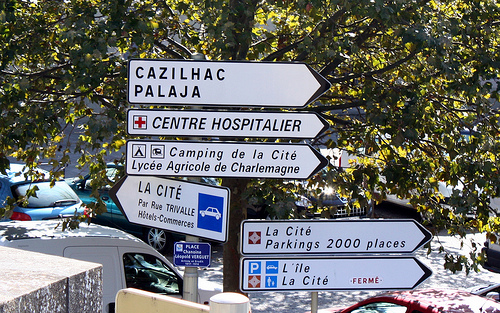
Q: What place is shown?
A: It is a parking lot.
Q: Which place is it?
A: It is a parking lot.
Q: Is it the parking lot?
A: Yes, it is the parking lot.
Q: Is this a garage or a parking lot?
A: It is a parking lot.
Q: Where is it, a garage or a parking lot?
A: It is a parking lot.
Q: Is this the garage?
A: No, it is the parking lot.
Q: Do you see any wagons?
A: No, there are no wagons.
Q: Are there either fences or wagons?
A: No, there are no wagons or fences.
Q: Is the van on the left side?
A: Yes, the van is on the left of the image.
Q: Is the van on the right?
A: No, the van is on the left of the image.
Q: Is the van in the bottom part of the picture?
A: Yes, the van is in the bottom of the image.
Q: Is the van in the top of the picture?
A: No, the van is in the bottom of the image.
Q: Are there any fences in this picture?
A: No, there are no fences.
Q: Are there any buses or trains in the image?
A: No, there are no buses or trains.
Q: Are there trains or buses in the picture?
A: No, there are no buses or trains.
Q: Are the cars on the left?
A: Yes, the cars are on the left of the image.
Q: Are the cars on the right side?
A: No, the cars are on the left of the image.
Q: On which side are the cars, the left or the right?
A: The cars are on the left of the image.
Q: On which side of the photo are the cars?
A: The cars are on the left of the image.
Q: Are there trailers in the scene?
A: No, there are no trailers.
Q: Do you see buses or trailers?
A: No, there are no trailers or buses.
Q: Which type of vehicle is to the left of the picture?
A: The vehicle is a car.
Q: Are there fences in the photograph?
A: No, there are no fences.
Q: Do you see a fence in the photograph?
A: No, there are no fences.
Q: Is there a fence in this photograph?
A: No, there are no fences.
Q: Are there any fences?
A: No, there are no fences.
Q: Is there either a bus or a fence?
A: No, there are no fences or buses.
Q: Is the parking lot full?
A: Yes, the parking lot is full.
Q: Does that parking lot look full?
A: Yes, the parking lot is full.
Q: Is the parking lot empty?
A: No, the parking lot is full.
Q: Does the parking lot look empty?
A: No, the parking lot is full.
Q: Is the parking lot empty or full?
A: The parking lot is full.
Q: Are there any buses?
A: No, there are no buses.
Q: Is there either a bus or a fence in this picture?
A: No, there are no buses or fences.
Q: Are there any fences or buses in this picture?
A: No, there are no buses or fences.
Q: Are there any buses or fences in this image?
A: No, there are no buses or fences.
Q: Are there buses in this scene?
A: No, there are no buses.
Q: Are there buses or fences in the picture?
A: No, there are no buses or fences.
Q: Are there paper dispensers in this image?
A: No, there are no paper dispensers.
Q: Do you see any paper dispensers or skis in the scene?
A: No, there are no paper dispensers or skis.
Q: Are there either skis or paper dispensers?
A: No, there are no paper dispensers or skis.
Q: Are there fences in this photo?
A: No, there are no fences.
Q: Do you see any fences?
A: No, there are no fences.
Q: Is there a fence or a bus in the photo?
A: No, there are no fences or buses.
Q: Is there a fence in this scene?
A: No, there are no fences.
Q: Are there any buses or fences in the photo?
A: No, there are no fences or buses.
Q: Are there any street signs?
A: Yes, there is a street sign.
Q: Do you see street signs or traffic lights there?
A: Yes, there is a street sign.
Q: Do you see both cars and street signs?
A: Yes, there are both a street sign and a car.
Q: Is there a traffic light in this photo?
A: No, there are no traffic lights.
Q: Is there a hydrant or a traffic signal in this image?
A: No, there are no traffic lights or fire hydrants.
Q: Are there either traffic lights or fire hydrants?
A: No, there are no traffic lights or fire hydrants.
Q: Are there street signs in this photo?
A: Yes, there is a street sign.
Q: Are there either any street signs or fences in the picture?
A: Yes, there is a street sign.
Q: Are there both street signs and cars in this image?
A: Yes, there are both a street sign and a car.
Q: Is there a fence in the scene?
A: No, there are no fences.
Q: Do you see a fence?
A: No, there are no fences.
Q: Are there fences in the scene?
A: No, there are no fences.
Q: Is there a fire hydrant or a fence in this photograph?
A: No, there are no fences or fire hydrants.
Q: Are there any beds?
A: No, there are no beds.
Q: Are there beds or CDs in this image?
A: No, there are no beds or cds.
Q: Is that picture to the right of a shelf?
A: No, the picture is to the right of the car.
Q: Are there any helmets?
A: No, there are no helmets.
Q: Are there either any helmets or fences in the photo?
A: No, there are no helmets or fences.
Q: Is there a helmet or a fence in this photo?
A: No, there are no helmets or fences.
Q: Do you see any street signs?
A: Yes, there is a street sign.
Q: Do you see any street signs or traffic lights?
A: Yes, there is a street sign.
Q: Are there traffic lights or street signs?
A: Yes, there is a street sign.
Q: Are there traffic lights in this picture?
A: No, there are no traffic lights.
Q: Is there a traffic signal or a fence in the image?
A: No, there are no traffic lights or fences.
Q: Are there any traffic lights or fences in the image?
A: No, there are no traffic lights or fences.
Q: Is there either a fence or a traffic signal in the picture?
A: No, there are no traffic lights or fences.